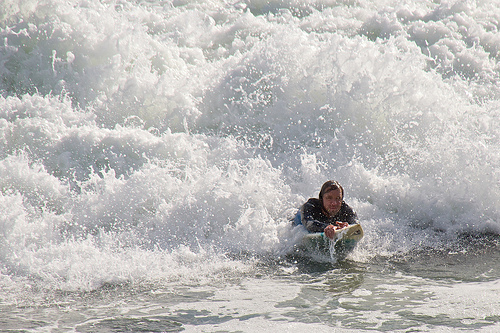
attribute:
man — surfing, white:
[295, 178, 354, 238]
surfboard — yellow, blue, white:
[307, 222, 365, 265]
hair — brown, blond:
[318, 178, 345, 217]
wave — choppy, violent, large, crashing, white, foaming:
[1, 5, 496, 288]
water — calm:
[6, 231, 500, 332]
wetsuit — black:
[290, 197, 353, 233]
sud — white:
[173, 271, 303, 333]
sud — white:
[352, 274, 499, 332]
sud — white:
[12, 289, 160, 333]